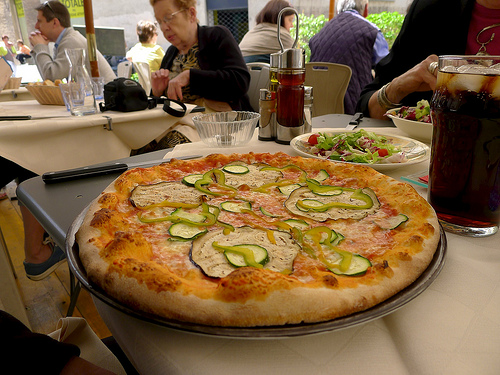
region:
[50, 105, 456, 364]
The pizza on the table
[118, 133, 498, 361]
the tablecloth under the pizza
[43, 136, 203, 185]
the knife beside the pizza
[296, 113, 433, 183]
the salad in the plate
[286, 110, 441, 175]
the plate is white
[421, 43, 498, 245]
the glass of soda on the table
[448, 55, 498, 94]
ice cubes in the soda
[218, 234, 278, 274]
a cucumber on the pizza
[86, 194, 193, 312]
the crust is toasted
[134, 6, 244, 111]
the woman wearing glasses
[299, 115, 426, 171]
Salad in a bowl.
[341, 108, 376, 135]
Knife on the table.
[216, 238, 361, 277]
Cucumbers on the pizza.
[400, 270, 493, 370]
The tablecloth is white.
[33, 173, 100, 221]
The table is grey.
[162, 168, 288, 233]
Peppers on the pizza.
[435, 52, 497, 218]
Dark fluid in the glass.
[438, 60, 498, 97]
Ice in the glass.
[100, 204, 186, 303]
Yellow cheese on the crust.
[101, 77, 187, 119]
Bag on the table.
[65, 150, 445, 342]
The plate holds a pizza.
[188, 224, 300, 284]
Vegetables are on the pizza.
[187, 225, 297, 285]
The vegetables are sliced.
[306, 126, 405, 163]
A salad is behind the pizza.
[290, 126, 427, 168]
The salad is on a plate.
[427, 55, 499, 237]
A glass is on the table.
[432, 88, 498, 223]
Coca-cola is in the glass.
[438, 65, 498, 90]
Ice cubes are in the glass.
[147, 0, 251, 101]
A woman sits at the table.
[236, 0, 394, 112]
Two people sit in the background.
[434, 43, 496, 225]
soda is in the glass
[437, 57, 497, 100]
ice is in the soda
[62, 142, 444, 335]
the pizza is round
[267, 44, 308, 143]
the oil and vinager are on the table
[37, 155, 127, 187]
the knife handle is black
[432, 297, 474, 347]
the table cloth is tan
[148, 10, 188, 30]
the woman is wearing glasses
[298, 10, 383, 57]
the vest is purple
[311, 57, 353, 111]
the chair is tan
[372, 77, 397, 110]
the bracelets are silver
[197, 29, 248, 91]
Person wearing black sweater.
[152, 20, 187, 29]
Glasses on person's face.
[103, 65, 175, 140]
Black bag sitting on table.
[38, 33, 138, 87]
Person wearing gray shirt.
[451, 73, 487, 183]
Dark liquid in glass on table.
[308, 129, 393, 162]
Tomatoes on salad on table.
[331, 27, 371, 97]
Person wearing black vest.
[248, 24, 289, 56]
Person wearing tan shirt.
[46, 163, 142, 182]
Black handle on knife on table.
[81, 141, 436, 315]
Pizza sitting on tray on table.